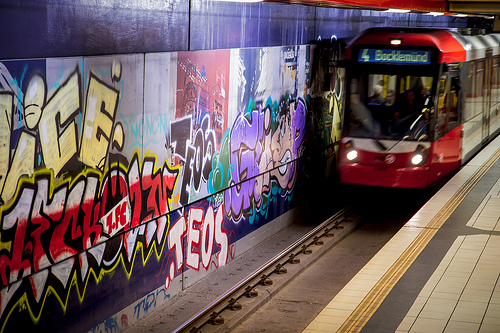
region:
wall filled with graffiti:
[1, 46, 319, 331]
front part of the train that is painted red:
[340, 23, 462, 198]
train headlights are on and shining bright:
[344, 141, 431, 175]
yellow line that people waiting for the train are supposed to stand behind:
[328, 138, 498, 332]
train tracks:
[144, 216, 369, 331]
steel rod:
[178, 201, 358, 331]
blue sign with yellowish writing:
[363, 43, 439, 63]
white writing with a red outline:
[158, 201, 248, 273]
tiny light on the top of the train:
[389, 36, 404, 48]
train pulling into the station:
[336, 24, 497, 213]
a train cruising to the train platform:
[339, 26, 499, 201]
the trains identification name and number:
[358, 45, 430, 61]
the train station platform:
[300, 186, 499, 331]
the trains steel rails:
[171, 202, 338, 332]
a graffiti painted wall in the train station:
[0, 37, 340, 309]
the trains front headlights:
[345, 148, 357, 161]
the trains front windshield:
[346, 70, 431, 139]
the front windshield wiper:
[387, 95, 429, 153]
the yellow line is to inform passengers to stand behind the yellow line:
[335, 143, 498, 330]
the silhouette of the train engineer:
[392, 76, 430, 137]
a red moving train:
[325, 20, 495, 210]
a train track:
[175, 185, 370, 325]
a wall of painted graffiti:
[0, 35, 320, 325]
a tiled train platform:
[290, 130, 490, 330]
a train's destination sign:
[351, 42, 431, 62]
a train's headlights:
[340, 145, 425, 165]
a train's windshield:
[340, 61, 435, 141]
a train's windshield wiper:
[380, 101, 425, 151]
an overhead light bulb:
[375, 5, 405, 15]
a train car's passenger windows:
[464, 50, 498, 122]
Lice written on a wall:
[11, 87, 156, 190]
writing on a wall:
[20, 170, 230, 308]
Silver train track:
[267, 215, 385, 322]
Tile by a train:
[416, 206, 499, 313]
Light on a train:
[340, 143, 371, 176]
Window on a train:
[344, 68, 432, 135]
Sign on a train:
[351, 41, 443, 76]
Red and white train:
[353, 19, 462, 215]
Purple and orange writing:
[203, 92, 332, 221]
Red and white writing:
[23, 183, 216, 284]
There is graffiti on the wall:
[8, 52, 319, 319]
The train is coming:
[326, 21, 498, 227]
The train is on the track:
[143, 25, 499, 327]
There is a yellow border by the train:
[301, 111, 498, 331]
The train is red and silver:
[340, 22, 497, 202]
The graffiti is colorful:
[6, 62, 330, 238]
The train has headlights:
[331, 137, 468, 223]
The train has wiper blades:
[341, 86, 433, 179]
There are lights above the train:
[379, 0, 481, 25]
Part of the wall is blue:
[16, 0, 474, 56]